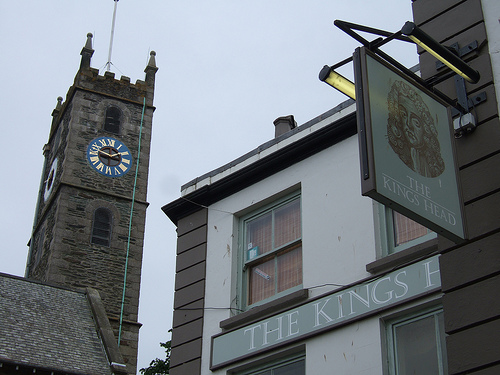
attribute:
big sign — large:
[353, 45, 470, 245]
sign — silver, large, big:
[353, 45, 470, 245]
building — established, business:
[158, 6, 495, 374]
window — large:
[234, 188, 310, 316]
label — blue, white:
[245, 246, 261, 263]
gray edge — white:
[179, 61, 421, 198]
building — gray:
[2, 34, 158, 373]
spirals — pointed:
[42, 32, 161, 111]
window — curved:
[102, 100, 122, 136]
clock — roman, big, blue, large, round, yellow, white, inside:
[83, 135, 134, 178]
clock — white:
[43, 158, 59, 201]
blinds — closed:
[246, 201, 303, 304]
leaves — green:
[139, 328, 172, 375]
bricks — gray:
[71, 248, 140, 300]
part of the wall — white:
[155, 81, 496, 366]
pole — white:
[102, 1, 125, 77]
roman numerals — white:
[88, 134, 130, 180]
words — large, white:
[242, 260, 446, 350]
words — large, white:
[382, 166, 459, 228]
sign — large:
[210, 250, 440, 369]